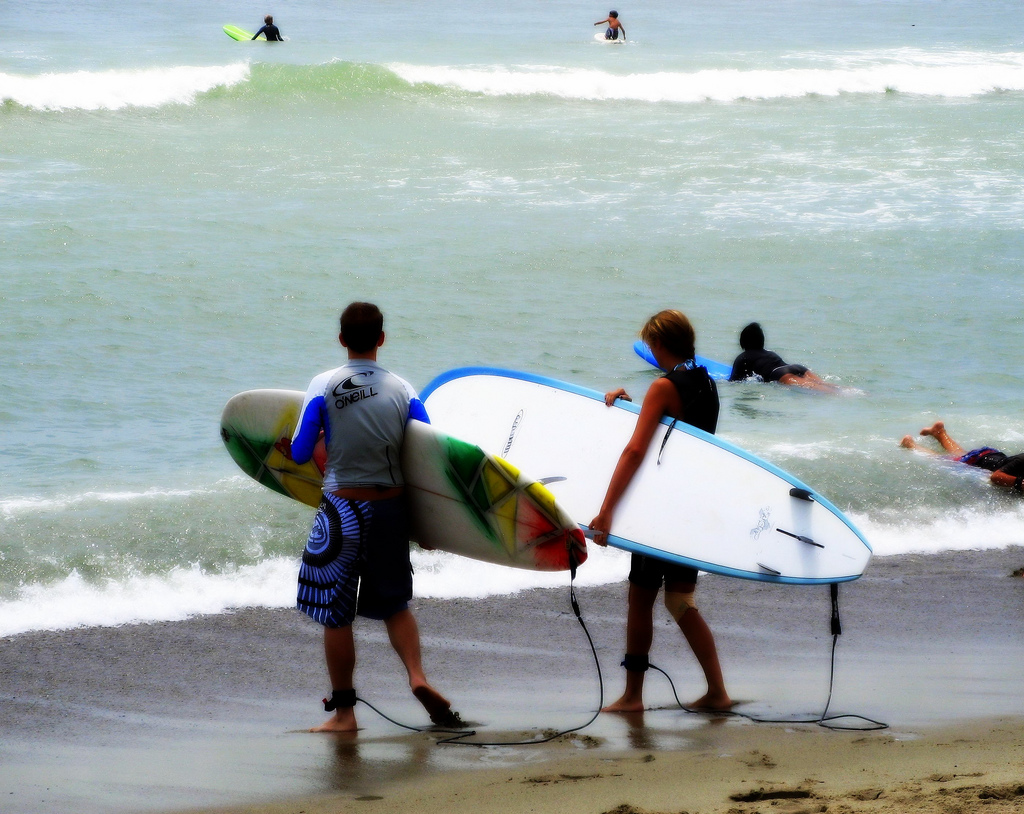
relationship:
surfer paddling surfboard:
[214, 6, 291, 49] [218, 7, 266, 49]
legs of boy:
[309, 606, 464, 728] [290, 301, 452, 731]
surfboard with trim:
[415, 358, 868, 575] [434, 348, 519, 379]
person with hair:
[725, 320, 840, 393] [616, 290, 707, 362]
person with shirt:
[725, 320, 840, 393] [659, 351, 731, 436]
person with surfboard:
[725, 320, 840, 393] [389, 351, 878, 585]